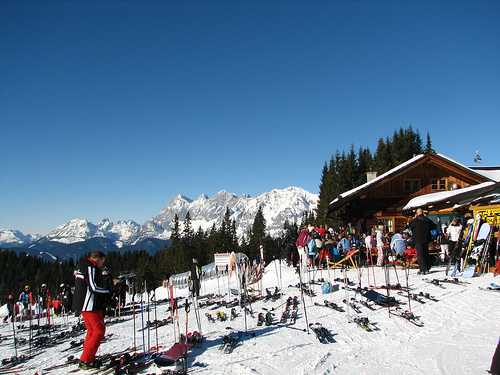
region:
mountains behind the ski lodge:
[3, 178, 330, 262]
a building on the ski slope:
[321, 146, 498, 237]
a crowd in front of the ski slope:
[294, 209, 479, 273]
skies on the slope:
[114, 267, 465, 345]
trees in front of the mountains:
[2, 192, 332, 304]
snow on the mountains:
[0, 177, 320, 262]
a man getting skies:
[70, 245, 112, 367]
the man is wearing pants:
[75, 303, 108, 368]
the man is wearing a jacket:
[71, 256, 112, 312]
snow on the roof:
[329, 144, 499, 208]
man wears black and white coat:
[72, 255, 117, 313]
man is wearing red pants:
[67, 313, 112, 358]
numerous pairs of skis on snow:
[132, 220, 464, 365]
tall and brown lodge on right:
[321, 143, 499, 266]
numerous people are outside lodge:
[277, 221, 499, 279]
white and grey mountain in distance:
[169, 188, 317, 240]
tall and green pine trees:
[135, 190, 288, 260]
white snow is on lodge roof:
[341, 157, 494, 198]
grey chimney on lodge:
[359, 165, 387, 176]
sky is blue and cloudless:
[99, 65, 216, 165]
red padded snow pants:
[81, 311, 104, 360]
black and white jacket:
[83, 264, 107, 309]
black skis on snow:
[312, 320, 330, 344]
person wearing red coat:
[297, 224, 310, 261]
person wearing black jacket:
[188, 257, 202, 294]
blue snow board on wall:
[468, 223, 490, 279]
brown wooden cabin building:
[323, 156, 499, 266]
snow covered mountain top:
[51, 189, 317, 241]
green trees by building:
[310, 125, 423, 221]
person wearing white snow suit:
[376, 224, 386, 264]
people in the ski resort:
[0, 132, 493, 364]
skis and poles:
[213, 253, 395, 343]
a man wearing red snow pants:
[66, 245, 118, 372]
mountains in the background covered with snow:
[21, 187, 306, 233]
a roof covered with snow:
[413, 178, 456, 205]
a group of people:
[296, 217, 390, 269]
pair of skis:
[350, 313, 382, 335]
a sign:
[210, 245, 232, 267]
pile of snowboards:
[464, 214, 491, 270]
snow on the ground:
[382, 337, 445, 369]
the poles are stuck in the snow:
[9, 229, 437, 374]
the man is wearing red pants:
[70, 304, 112, 367]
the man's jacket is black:
[70, 257, 117, 315]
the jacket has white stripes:
[71, 255, 121, 316]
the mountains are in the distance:
[1, 183, 324, 269]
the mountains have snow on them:
[1, 181, 311, 262]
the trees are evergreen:
[1, 124, 440, 316]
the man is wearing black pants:
[410, 241, 434, 276]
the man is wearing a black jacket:
[408, 213, 436, 250]